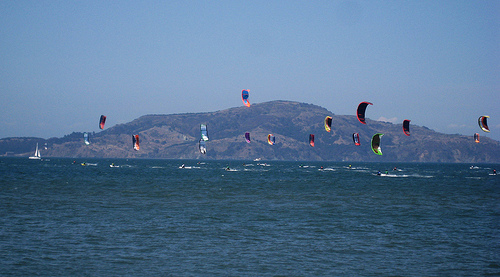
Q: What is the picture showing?
A: It is showing an ocean.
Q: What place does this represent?
A: It represents the ocean.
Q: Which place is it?
A: It is an ocean.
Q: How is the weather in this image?
A: It is cloudless.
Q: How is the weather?
A: It is cloudless.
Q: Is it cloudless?
A: Yes, it is cloudless.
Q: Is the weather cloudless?
A: Yes, it is cloudless.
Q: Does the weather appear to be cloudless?
A: Yes, it is cloudless.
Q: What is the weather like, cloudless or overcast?
A: It is cloudless.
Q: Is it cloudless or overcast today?
A: It is cloudless.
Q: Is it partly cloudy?
A: No, it is cloudless.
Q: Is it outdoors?
A: Yes, it is outdoors.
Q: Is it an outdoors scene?
A: Yes, it is outdoors.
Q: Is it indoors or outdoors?
A: It is outdoors.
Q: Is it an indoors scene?
A: No, it is outdoors.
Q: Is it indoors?
A: No, it is outdoors.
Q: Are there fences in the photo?
A: No, there are no fences.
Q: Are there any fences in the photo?
A: No, there are no fences.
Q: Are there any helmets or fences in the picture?
A: No, there are no fences or helmets.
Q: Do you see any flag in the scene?
A: No, there are no flags.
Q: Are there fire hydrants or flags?
A: No, there are no flags or fire hydrants.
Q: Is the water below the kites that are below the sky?
A: Yes, the water is below the kites.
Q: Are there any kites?
A: Yes, there is a kite.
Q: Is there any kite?
A: Yes, there is a kite.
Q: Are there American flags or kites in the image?
A: Yes, there is a kite.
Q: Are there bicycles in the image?
A: No, there are no bicycles.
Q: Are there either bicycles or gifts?
A: No, there are no bicycles or gifts.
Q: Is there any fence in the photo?
A: No, there are no fences.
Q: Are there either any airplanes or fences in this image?
A: No, there are no fences or airplanes.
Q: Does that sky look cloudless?
A: Yes, the sky is cloudless.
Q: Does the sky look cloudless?
A: Yes, the sky is cloudless.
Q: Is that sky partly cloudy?
A: No, the sky is cloudless.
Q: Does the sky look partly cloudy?
A: No, the sky is cloudless.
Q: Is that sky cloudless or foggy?
A: The sky is cloudless.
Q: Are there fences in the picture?
A: No, there are no fences.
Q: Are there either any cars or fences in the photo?
A: No, there are no fences or cars.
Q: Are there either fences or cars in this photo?
A: No, there are no fences or cars.